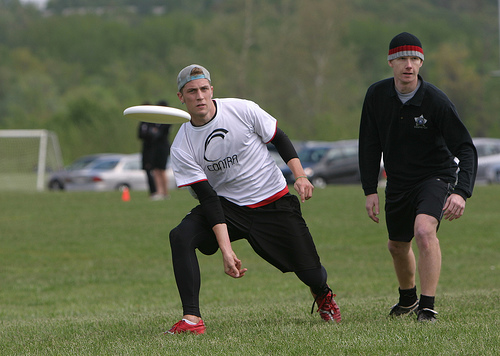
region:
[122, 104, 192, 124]
a Frisbee disk in the air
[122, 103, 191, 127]
a white Frisbee disk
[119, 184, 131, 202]
an orange cone on the field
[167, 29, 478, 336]
two men on a field in a park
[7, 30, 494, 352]
two men playing Frisbee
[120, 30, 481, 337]
two Frisbee players at the park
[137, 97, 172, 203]
two persons standing on the ground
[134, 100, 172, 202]
two people standing a field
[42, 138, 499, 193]
cars parked in a parking lot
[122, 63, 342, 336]
a Frisbee player in a white t-shirt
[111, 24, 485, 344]
two men playing ultimate frisbee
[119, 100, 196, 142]
a white frisbee flying through the air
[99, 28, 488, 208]
two men near a frisbee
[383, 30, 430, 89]
a man wearing a cap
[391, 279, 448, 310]
a pair of black socks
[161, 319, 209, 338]
a red and white tennis shoe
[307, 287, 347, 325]
a red and white tennis shoe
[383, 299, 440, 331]
a pair of black tennis shoes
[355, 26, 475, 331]
man standing in ready position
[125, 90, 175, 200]
spectators watching the sport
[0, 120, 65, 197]
white frame soccer net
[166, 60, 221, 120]
man wearing white baseball cap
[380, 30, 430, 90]
man wearing multi color cap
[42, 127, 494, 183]
cars in parking lot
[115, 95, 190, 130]
white frisbee flying through the air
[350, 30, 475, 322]
man prepares to sprint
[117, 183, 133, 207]
orange cone defines playing field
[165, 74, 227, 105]
the eyes of a man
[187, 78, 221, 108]
the nose of a man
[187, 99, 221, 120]
the lips of a man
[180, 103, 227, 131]
the chin of a man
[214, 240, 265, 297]
the hand of a man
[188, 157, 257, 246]
the arm of a man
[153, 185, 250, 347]
the leg of a man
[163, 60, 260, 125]
a man wearing a hat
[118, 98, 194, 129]
white frisbee in the air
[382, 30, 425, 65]
ski cap on a man's head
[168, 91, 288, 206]
white and black tee shirt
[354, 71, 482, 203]
black long sleeved shirt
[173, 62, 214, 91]
grey hat on a man's head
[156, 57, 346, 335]
man wearing a white shirt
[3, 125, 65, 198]
soccer net in a field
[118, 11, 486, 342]
a couple of people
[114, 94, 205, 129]
a frisbee in the air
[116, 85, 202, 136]
the frisbee is whie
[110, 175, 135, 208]
cone in the background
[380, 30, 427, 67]
man wearing a hat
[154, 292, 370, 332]
a pair of red shoea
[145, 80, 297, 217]
man wearing a white shirt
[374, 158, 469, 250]
black pair of pants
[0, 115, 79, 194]
net in the background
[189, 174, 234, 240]
black sleeve on shirt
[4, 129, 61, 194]
A white soccer goal.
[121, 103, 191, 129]
A white frisbee.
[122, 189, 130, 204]
A yellow cone.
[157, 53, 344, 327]
A person wearing a backwards cap.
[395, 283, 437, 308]
A pair of black socks.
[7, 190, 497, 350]
A grassy field.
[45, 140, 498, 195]
Parked vehicles.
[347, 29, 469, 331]
A man wearing a long sleeve shirt.